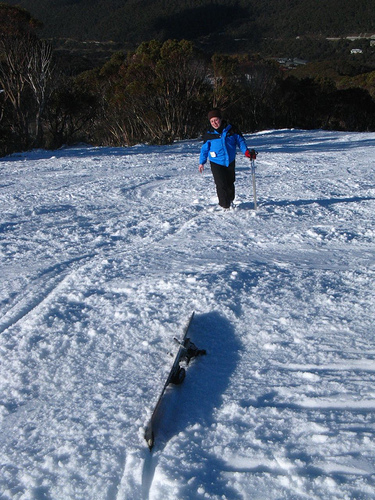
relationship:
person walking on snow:
[199, 110, 257, 208] [0, 125, 373, 498]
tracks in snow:
[2, 247, 95, 319] [251, 286, 358, 393]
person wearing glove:
[199, 110, 257, 208] [245, 149, 258, 159]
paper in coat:
[208, 150, 216, 158] [200, 123, 247, 167]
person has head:
[199, 110, 257, 208] [207, 109, 223, 128]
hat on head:
[206, 108, 220, 119] [207, 109, 223, 128]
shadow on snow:
[151, 135, 373, 154] [0, 125, 373, 498]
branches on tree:
[103, 92, 204, 145] [93, 37, 216, 147]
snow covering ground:
[0, 125, 373, 498] [0, 30, 370, 497]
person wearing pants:
[199, 110, 257, 208] [209, 157, 237, 209]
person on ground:
[195, 106, 259, 212] [0, 126, 375, 498]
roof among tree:
[269, 53, 316, 71] [299, 73, 342, 130]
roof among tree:
[269, 53, 316, 71] [262, 71, 327, 134]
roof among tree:
[269, 53, 316, 71] [215, 47, 284, 137]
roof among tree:
[269, 53, 316, 71] [297, 33, 330, 64]